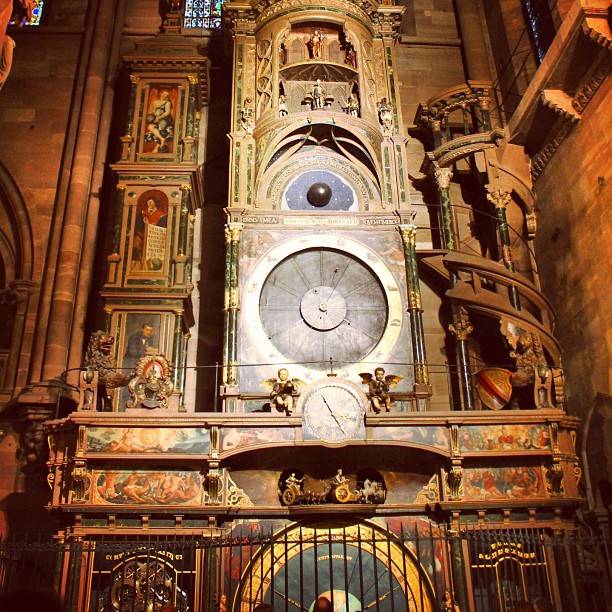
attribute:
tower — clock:
[215, 7, 443, 428]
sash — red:
[476, 369, 511, 406]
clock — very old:
[236, 224, 414, 394]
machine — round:
[111, 557, 178, 610]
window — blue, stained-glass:
[184, 1, 224, 28]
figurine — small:
[344, 45, 357, 67]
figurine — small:
[303, 27, 324, 59]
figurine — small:
[281, 38, 293, 64]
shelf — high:
[279, 57, 362, 83]